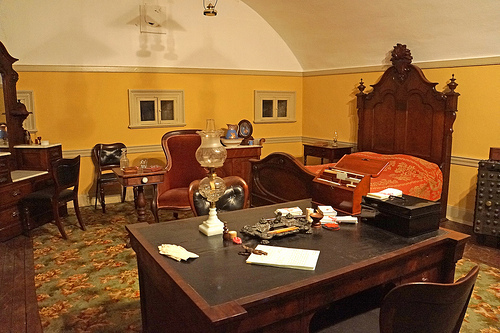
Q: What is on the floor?
A: Carpet.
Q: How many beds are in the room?
A: One.